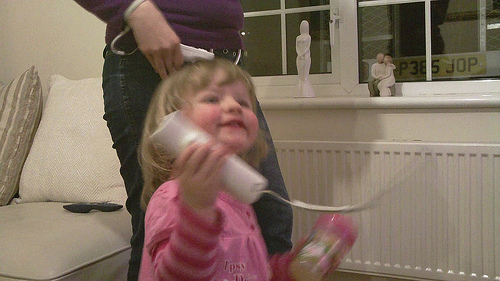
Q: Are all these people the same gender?
A: No, they are both male and female.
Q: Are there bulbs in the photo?
A: No, there are no bulbs.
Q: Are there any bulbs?
A: No, there are no bulbs.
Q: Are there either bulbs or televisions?
A: No, there are no bulbs or televisions.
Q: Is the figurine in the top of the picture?
A: Yes, the figurine is in the top of the image.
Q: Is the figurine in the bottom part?
A: No, the figurine is in the top of the image.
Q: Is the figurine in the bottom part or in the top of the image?
A: The figurine is in the top of the image.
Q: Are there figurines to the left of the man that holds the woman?
A: Yes, there is a figurine to the left of the man.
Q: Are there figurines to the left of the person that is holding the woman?
A: Yes, there is a figurine to the left of the man.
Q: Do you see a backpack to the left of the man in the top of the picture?
A: No, there is a figurine to the left of the man.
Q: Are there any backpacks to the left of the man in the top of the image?
A: No, there is a figurine to the left of the man.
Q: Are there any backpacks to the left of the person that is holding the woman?
A: No, there is a figurine to the left of the man.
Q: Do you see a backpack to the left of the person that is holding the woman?
A: No, there is a figurine to the left of the man.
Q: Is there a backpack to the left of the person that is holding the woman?
A: No, there is a figurine to the left of the man.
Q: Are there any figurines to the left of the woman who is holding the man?
A: Yes, there is a figurine to the left of the woman.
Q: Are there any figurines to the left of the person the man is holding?
A: Yes, there is a figurine to the left of the woman.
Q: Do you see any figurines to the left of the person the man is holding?
A: Yes, there is a figurine to the left of the woman.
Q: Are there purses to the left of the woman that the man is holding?
A: No, there is a figurine to the left of the woman.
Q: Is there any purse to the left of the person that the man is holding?
A: No, there is a figurine to the left of the woman.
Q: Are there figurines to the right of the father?
A: Yes, there is a figurine to the right of the father.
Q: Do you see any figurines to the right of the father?
A: Yes, there is a figurine to the right of the father.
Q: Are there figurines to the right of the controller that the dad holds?
A: Yes, there is a figurine to the right of the controller.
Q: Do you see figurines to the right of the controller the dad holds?
A: Yes, there is a figurine to the right of the controller.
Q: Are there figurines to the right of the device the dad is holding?
A: Yes, there is a figurine to the right of the controller.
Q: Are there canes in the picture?
A: No, there are no canes.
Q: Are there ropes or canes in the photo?
A: No, there are no canes or ropes.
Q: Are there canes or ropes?
A: No, there are no canes or ropes.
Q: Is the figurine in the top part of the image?
A: Yes, the figurine is in the top of the image.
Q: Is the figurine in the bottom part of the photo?
A: No, the figurine is in the top of the image.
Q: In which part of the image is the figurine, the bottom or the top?
A: The figurine is in the top of the image.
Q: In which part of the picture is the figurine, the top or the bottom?
A: The figurine is in the top of the image.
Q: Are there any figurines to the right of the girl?
A: Yes, there is a figurine to the right of the girl.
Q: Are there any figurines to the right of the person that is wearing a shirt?
A: Yes, there is a figurine to the right of the girl.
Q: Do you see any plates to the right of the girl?
A: No, there is a figurine to the right of the girl.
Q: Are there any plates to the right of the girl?
A: No, there is a figurine to the right of the girl.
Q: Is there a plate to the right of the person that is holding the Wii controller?
A: No, there is a figurine to the right of the girl.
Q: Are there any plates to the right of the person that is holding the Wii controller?
A: No, there is a figurine to the right of the girl.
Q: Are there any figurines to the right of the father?
A: Yes, there is a figurine to the right of the father.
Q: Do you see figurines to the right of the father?
A: Yes, there is a figurine to the right of the father.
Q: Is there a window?
A: Yes, there is a window.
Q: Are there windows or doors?
A: Yes, there is a window.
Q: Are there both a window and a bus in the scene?
A: No, there is a window but no buses.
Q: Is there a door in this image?
A: No, there are no doors.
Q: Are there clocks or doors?
A: No, there are no doors or clocks.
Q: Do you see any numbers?
A: Yes, there are numbers.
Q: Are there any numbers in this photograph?
A: Yes, there are numbers.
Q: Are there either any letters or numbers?
A: Yes, there are numbers.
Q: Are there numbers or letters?
A: Yes, there are numbers.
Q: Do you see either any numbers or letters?
A: Yes, there are numbers.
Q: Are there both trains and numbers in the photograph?
A: No, there are numbers but no trains.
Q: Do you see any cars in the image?
A: No, there are no cars.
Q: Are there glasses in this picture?
A: No, there are no glasses.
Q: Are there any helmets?
A: No, there are no helmets.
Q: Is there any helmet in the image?
A: No, there are no helmets.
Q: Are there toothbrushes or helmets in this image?
A: No, there are no helmets or toothbrushes.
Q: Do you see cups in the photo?
A: Yes, there is a cup.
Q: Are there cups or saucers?
A: Yes, there is a cup.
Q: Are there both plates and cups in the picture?
A: No, there is a cup but no plates.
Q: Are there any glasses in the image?
A: No, there are no glasses.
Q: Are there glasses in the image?
A: No, there are no glasses.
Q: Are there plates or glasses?
A: No, there are no glasses or plates.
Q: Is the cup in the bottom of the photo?
A: Yes, the cup is in the bottom of the image.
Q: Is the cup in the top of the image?
A: No, the cup is in the bottom of the image.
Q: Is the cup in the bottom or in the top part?
A: The cup is in the bottom of the image.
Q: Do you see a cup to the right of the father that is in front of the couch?
A: Yes, there is a cup to the right of the father.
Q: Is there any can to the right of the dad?
A: No, there is a cup to the right of the dad.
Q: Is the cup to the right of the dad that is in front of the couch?
A: Yes, the cup is to the right of the father.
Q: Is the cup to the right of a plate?
A: No, the cup is to the right of the father.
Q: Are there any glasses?
A: No, there are no glasses.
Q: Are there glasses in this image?
A: No, there are no glasses.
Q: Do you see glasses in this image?
A: No, there are no glasses.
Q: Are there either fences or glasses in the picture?
A: No, there are no glasses or fences.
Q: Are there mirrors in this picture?
A: No, there are no mirrors.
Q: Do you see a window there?
A: Yes, there is a window.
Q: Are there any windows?
A: Yes, there is a window.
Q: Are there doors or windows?
A: Yes, there is a window.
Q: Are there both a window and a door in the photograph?
A: No, there is a window but no doors.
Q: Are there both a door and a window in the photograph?
A: No, there is a window but no doors.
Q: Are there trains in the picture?
A: No, there are no trains.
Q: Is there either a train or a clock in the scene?
A: No, there are no trains or clocks.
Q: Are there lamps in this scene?
A: No, there are no lamps.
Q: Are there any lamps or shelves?
A: No, there are no lamps or shelves.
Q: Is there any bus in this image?
A: No, there are no buses.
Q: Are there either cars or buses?
A: No, there are no buses or cars.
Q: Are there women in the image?
A: Yes, there is a woman.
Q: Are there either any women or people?
A: Yes, there is a woman.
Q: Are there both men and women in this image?
A: Yes, there are both a woman and men.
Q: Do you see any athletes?
A: No, there are no athletes.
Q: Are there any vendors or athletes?
A: No, there are no athletes or vendors.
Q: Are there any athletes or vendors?
A: No, there are no athletes or vendors.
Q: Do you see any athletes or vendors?
A: No, there are no athletes or vendors.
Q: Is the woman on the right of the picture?
A: Yes, the woman is on the right of the image.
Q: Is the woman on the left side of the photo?
A: No, the woman is on the right of the image.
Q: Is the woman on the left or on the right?
A: The woman is on the right of the image.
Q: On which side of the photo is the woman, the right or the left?
A: The woman is on the right of the image.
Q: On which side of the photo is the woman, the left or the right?
A: The woman is on the right of the image.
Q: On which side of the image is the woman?
A: The woman is on the right of the image.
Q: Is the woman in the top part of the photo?
A: Yes, the woman is in the top of the image.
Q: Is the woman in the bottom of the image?
A: No, the woman is in the top of the image.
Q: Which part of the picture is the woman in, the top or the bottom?
A: The woman is in the top of the image.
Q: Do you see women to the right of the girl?
A: Yes, there is a woman to the right of the girl.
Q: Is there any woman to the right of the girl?
A: Yes, there is a woman to the right of the girl.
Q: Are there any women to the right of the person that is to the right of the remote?
A: Yes, there is a woman to the right of the girl.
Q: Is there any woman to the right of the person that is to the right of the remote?
A: Yes, there is a woman to the right of the girl.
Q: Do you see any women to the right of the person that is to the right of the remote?
A: Yes, there is a woman to the right of the girl.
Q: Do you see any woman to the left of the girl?
A: No, the woman is to the right of the girl.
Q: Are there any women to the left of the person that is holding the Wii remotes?
A: No, the woman is to the right of the girl.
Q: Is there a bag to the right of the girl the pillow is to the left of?
A: No, there is a woman to the right of the girl.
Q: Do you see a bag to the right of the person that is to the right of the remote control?
A: No, there is a woman to the right of the girl.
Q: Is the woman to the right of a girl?
A: Yes, the woman is to the right of a girl.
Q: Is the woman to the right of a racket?
A: No, the woman is to the right of a girl.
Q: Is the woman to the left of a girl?
A: No, the woman is to the right of a girl.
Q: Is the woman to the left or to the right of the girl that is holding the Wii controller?
A: The woman is to the right of the girl.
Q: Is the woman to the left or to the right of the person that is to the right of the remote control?
A: The woman is to the right of the girl.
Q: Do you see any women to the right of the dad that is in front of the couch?
A: Yes, there is a woman to the right of the dad.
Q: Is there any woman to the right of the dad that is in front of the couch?
A: Yes, there is a woman to the right of the dad.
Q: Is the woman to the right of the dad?
A: Yes, the woman is to the right of the dad.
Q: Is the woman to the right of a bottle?
A: No, the woman is to the right of the dad.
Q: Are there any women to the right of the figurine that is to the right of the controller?
A: Yes, there is a woman to the right of the figurine.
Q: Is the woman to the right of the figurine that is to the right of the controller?
A: Yes, the woman is to the right of the figurine.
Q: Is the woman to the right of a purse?
A: No, the woman is to the right of the figurine.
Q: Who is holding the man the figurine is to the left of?
A: The woman is holding the man.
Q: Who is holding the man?
A: The woman is holding the man.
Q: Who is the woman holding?
A: The woman is holding the man.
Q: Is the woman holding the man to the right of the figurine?
A: Yes, the woman is holding the man.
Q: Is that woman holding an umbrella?
A: No, the woman is holding the man.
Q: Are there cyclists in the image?
A: No, there are no cyclists.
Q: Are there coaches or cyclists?
A: No, there are no cyclists or coaches.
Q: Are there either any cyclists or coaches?
A: No, there are no cyclists or coaches.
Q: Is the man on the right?
A: Yes, the man is on the right of the image.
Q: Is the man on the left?
A: No, the man is on the right of the image.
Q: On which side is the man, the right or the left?
A: The man is on the right of the image.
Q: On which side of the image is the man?
A: The man is on the right of the image.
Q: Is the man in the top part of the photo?
A: Yes, the man is in the top of the image.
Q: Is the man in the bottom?
A: No, the man is in the top of the image.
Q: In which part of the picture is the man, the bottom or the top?
A: The man is in the top of the image.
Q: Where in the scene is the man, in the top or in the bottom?
A: The man is in the top of the image.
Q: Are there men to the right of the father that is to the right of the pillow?
A: Yes, there is a man to the right of the father.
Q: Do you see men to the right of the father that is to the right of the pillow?
A: Yes, there is a man to the right of the father.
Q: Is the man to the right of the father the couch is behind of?
A: Yes, the man is to the right of the dad.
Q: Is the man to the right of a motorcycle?
A: No, the man is to the right of the dad.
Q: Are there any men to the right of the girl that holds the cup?
A: Yes, there is a man to the right of the girl.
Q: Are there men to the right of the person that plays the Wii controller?
A: Yes, there is a man to the right of the girl.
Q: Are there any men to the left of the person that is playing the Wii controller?
A: No, the man is to the right of the girl.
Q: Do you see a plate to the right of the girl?
A: No, there is a man to the right of the girl.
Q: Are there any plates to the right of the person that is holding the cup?
A: No, there is a man to the right of the girl.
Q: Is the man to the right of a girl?
A: Yes, the man is to the right of a girl.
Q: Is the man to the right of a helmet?
A: No, the man is to the right of a girl.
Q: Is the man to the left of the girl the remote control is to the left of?
A: No, the man is to the right of the girl.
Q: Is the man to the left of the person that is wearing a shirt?
A: No, the man is to the right of the girl.